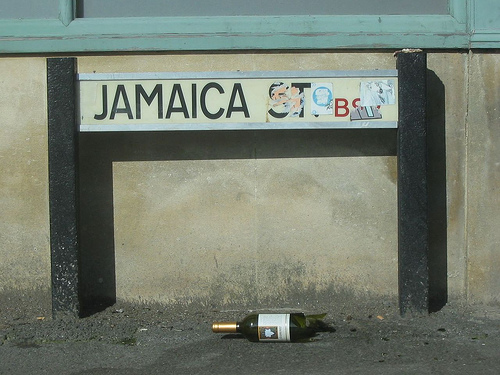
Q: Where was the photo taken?
A: Jamaica street.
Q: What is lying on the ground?
A: Liquor bottle.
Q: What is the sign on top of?
A: Black post.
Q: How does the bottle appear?
A: Broken.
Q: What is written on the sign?
A: Graffiti.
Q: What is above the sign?
A: Green paint.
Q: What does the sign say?
A: "Jamaica St.".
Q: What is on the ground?
A: A wine bottle.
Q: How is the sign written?
A: In black uppercase font.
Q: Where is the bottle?
A: Under the sign.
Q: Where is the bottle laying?
A: On the ground.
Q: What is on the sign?
A: Lettering and stickers.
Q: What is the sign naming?
A: The street.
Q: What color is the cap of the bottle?
A: Gold.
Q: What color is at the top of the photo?
A: Turquoise.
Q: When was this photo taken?
A: Day time.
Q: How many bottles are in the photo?
A: 1.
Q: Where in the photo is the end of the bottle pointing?
A: To the left.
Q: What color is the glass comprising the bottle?
A: Green.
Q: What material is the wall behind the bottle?
A: Concrete.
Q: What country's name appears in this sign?
A: Jamaica.